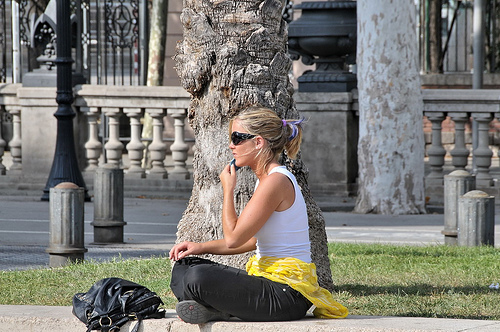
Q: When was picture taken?
A: Daytime.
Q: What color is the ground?
A: Green.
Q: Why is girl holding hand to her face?
A: Phone.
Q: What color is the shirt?
A: White.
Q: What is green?
A: Grass.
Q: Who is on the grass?
A: Lady.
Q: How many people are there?
A: One.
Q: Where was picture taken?
A: At a city park.